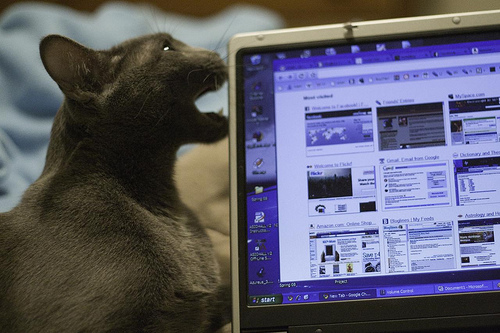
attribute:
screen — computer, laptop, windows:
[253, 95, 476, 248]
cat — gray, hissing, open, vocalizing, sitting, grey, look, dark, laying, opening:
[32, 15, 255, 209]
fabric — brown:
[111, 16, 137, 34]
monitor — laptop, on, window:
[240, 43, 486, 277]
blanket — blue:
[87, 0, 131, 42]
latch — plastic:
[328, 17, 359, 40]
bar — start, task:
[242, 287, 293, 323]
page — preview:
[282, 42, 399, 101]